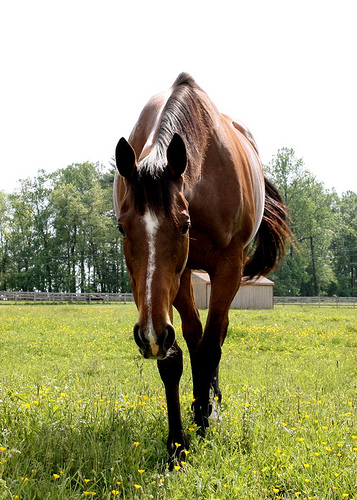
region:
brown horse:
[100, 75, 266, 462]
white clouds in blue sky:
[281, 51, 309, 91]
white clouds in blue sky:
[241, 60, 277, 102]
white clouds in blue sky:
[302, 69, 333, 120]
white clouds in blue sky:
[207, 40, 246, 60]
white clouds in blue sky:
[294, 51, 355, 106]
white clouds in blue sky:
[23, 74, 65, 113]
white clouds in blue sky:
[70, 87, 109, 113]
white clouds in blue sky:
[41, 73, 85, 118]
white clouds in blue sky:
[7, 64, 37, 90]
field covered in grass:
[26, 303, 117, 381]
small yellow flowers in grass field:
[109, 437, 164, 498]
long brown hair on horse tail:
[252, 175, 301, 286]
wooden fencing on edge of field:
[2, 286, 126, 305]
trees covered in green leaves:
[45, 155, 108, 282]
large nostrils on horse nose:
[126, 316, 177, 365]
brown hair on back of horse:
[147, 93, 209, 129]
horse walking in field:
[80, 77, 307, 464]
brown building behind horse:
[173, 259, 281, 318]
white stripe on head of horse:
[131, 203, 165, 347]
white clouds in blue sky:
[256, 25, 305, 84]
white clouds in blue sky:
[162, 33, 210, 54]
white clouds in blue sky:
[253, 4, 293, 37]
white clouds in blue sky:
[37, 41, 55, 76]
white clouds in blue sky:
[63, 25, 93, 57]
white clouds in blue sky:
[52, 44, 84, 74]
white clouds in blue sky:
[207, 25, 237, 55]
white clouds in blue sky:
[312, 75, 355, 108]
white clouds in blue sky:
[242, 20, 289, 61]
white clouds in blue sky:
[26, 16, 63, 45]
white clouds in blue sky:
[57, 39, 92, 57]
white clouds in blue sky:
[13, 65, 52, 102]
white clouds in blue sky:
[265, 62, 306, 109]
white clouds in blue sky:
[271, 35, 349, 96]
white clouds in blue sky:
[52, 42, 105, 94]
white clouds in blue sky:
[20, 64, 55, 148]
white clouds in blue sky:
[214, 10, 265, 48]